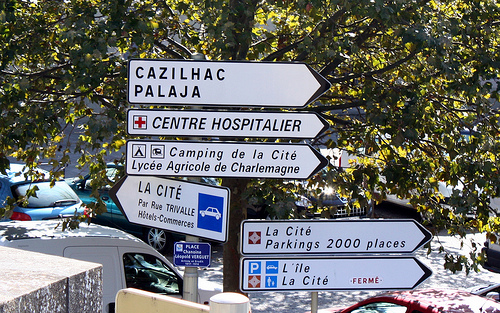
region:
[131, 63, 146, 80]
the letter C on a sign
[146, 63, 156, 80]
the letter A on a sign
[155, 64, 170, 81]
the letter Z on a sign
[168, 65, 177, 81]
the letter I on a sign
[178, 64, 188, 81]
the letter L on a sign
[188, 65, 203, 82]
the letter H on a sign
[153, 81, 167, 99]
the letter L on a sign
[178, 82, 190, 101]
the letter J on a sign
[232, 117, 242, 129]
the letter S on a sign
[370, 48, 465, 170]
tree behind the signs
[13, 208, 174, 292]
van parked in the lot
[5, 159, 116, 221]
cars parked in a lot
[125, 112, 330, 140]
direction sign for the hospital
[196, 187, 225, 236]
picture of car on the sign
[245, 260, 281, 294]
four pictures on the sign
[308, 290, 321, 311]
post with signs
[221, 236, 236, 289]
tree trunk behind sign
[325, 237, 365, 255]
number on the sign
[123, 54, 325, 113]
White sign directing to the Cazilhac Palaja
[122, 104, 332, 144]
Sign directing towards the hospital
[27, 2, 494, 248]
Tree behind signs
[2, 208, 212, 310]
white vehicle next to tree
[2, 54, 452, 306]
Parking lot with several cars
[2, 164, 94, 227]
Blue car in parking lot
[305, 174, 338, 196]
Sun reflecting on car hood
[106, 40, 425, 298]
Signs directing to different locations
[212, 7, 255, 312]
Tall tree trunk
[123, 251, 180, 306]
Dashboard of white vehicle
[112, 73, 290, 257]
La hospital signs with directions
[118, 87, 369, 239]
La hospital signs with directions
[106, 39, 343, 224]
La hospital signs with directions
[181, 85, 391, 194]
La hospital signs with directions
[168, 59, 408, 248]
La hospital signs with directions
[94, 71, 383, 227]
La hospital signs with directions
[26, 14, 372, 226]
La hospital signs with directions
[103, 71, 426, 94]
La hospital signs with directions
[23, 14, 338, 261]
La hospital signs with directions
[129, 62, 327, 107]
sign attached to the pole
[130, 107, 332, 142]
sign attached to the pole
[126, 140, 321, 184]
sign attached to the pole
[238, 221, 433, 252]
sign attached to the pole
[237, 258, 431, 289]
sign attached to the pole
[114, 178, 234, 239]
sign attached to the pole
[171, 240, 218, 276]
sign attached to the pole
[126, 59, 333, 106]
street sign attached to the pole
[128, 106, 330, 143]
street sign attached to the pole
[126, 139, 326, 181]
street sign attached to the pole